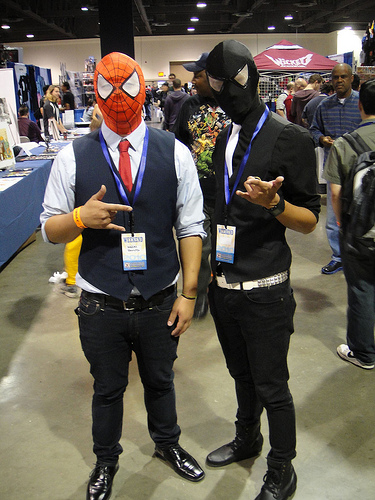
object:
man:
[39, 52, 207, 500]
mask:
[93, 51, 146, 135]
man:
[205, 39, 321, 500]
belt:
[215, 271, 289, 291]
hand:
[78, 184, 133, 232]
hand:
[236, 176, 285, 213]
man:
[319, 79, 375, 370]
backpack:
[337, 130, 375, 268]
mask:
[205, 38, 261, 124]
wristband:
[73, 205, 89, 229]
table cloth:
[0, 142, 74, 269]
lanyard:
[98, 124, 148, 212]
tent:
[252, 39, 339, 73]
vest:
[208, 110, 293, 284]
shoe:
[154, 439, 205, 482]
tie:
[225, 121, 242, 180]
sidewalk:
[0, 197, 375, 499]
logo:
[263, 53, 313, 68]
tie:
[116, 140, 133, 193]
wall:
[0, 30, 374, 93]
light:
[190, 17, 199, 23]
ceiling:
[0, 0, 375, 43]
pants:
[207, 280, 298, 462]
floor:
[0, 210, 375, 499]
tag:
[120, 232, 147, 272]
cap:
[182, 52, 209, 73]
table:
[0, 140, 75, 273]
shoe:
[85, 459, 120, 500]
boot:
[206, 420, 263, 467]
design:
[186, 104, 232, 181]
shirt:
[175, 93, 234, 186]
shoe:
[321, 258, 343, 276]